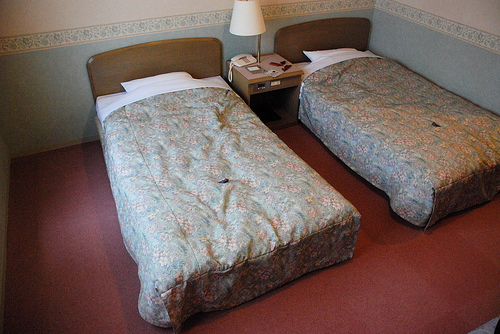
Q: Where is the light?
A: The table.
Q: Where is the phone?
A: On the nightstand.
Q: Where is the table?
A: In the middle.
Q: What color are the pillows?
A: White.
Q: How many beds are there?
A: Two.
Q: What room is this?
A: Bedroom.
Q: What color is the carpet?
A: Red.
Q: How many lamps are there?
A: One.